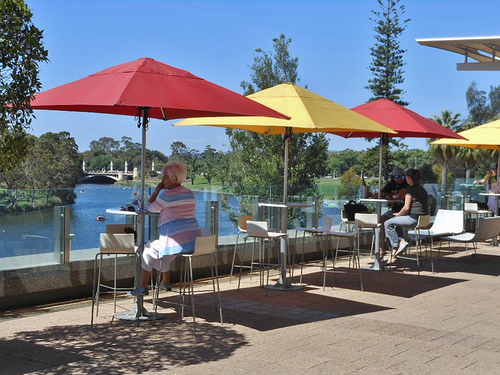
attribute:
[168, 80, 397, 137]
umbrella — yellow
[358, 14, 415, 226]
tree — tall